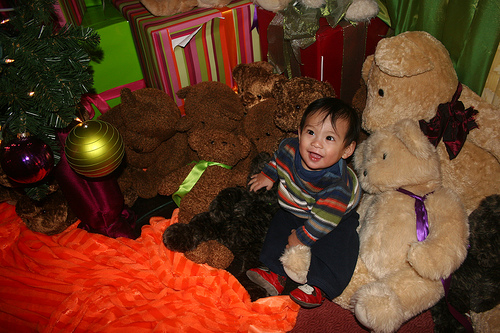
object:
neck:
[366, 183, 438, 194]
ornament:
[62, 119, 130, 181]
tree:
[0, 0, 110, 132]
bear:
[157, 128, 258, 268]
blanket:
[0, 201, 330, 333]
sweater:
[257, 138, 360, 249]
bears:
[89, 83, 183, 202]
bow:
[415, 97, 485, 163]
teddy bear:
[354, 28, 500, 213]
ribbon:
[172, 160, 234, 208]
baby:
[243, 97, 368, 310]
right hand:
[246, 172, 276, 193]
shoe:
[289, 280, 323, 310]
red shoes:
[246, 268, 288, 296]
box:
[256, 2, 384, 99]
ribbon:
[392, 185, 444, 244]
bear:
[328, 116, 474, 332]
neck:
[195, 158, 234, 169]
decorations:
[0, 0, 111, 188]